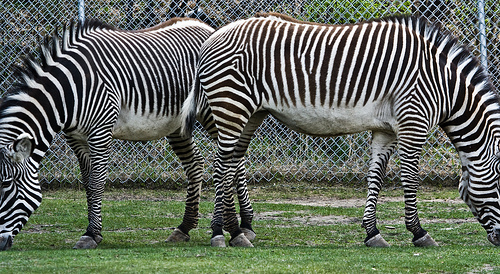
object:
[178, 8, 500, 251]
zebra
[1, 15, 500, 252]
zebras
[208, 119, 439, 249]
legs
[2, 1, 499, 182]
fence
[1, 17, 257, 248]
zebra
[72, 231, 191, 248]
hooves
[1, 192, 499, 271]
grass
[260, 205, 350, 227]
dirt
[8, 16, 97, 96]
mane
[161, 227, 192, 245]
hoof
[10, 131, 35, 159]
ear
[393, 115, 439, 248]
leg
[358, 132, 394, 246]
leg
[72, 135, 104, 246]
leg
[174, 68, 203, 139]
tail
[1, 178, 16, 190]
eye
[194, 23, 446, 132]
stripes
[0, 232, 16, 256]
mouth